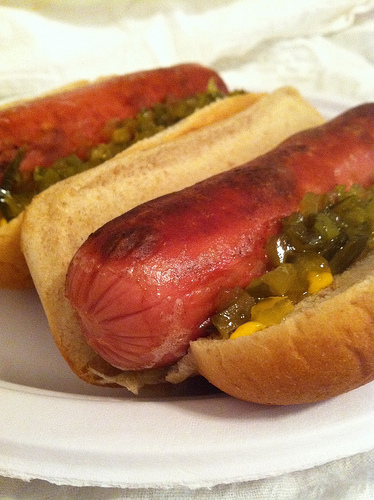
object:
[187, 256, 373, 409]
bun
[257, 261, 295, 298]
relish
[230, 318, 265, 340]
mustard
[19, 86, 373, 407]
hotdog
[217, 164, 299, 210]
marks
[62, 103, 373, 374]
skin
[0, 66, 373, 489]
plate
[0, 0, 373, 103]
cloth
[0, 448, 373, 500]
cloth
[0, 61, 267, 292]
hotdog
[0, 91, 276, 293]
bun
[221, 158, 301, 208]
blister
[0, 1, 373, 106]
napkin